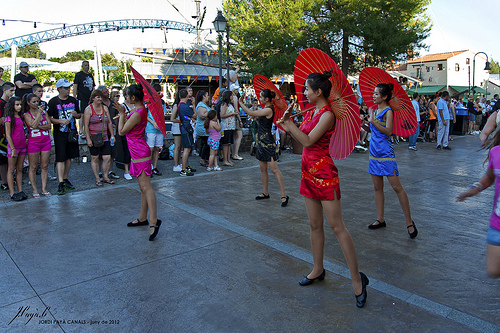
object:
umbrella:
[129, 61, 167, 140]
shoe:
[148, 216, 163, 242]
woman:
[279, 70, 372, 306]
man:
[46, 76, 83, 197]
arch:
[1, 17, 216, 58]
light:
[210, 9, 230, 34]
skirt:
[367, 105, 401, 177]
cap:
[53, 77, 75, 90]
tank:
[26, 107, 53, 144]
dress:
[297, 102, 344, 202]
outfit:
[122, 105, 154, 177]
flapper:
[249, 104, 278, 162]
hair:
[305, 67, 332, 102]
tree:
[221, 0, 434, 80]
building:
[388, 48, 496, 87]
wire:
[0, 16, 209, 73]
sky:
[0, 0, 500, 60]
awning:
[409, 84, 448, 93]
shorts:
[29, 138, 54, 153]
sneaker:
[57, 178, 66, 195]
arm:
[46, 102, 65, 124]